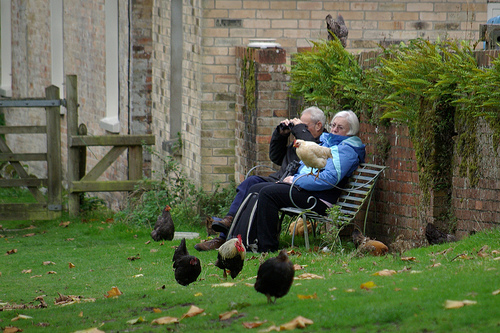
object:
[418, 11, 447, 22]
brick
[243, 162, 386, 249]
bench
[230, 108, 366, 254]
woman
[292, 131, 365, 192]
coat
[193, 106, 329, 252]
man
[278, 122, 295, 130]
binoculars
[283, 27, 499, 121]
shrubbery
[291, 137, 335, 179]
chicken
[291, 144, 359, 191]
arm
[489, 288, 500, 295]
leaf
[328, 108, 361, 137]
hair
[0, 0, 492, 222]
building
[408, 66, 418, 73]
leaves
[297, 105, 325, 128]
hair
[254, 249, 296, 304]
chicken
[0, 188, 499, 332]
grass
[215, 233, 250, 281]
chicken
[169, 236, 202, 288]
chicken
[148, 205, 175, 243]
chicken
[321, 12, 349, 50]
chicken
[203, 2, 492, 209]
wall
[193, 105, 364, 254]
couple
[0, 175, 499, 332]
farm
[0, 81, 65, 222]
fence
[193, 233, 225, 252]
shoes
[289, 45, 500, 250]
wall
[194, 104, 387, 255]
relaxing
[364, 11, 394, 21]
brick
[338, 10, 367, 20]
brick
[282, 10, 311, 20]
brick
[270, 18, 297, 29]
brick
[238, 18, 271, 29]
brick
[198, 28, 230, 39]
brick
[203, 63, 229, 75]
brick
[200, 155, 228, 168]
brick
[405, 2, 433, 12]
brick